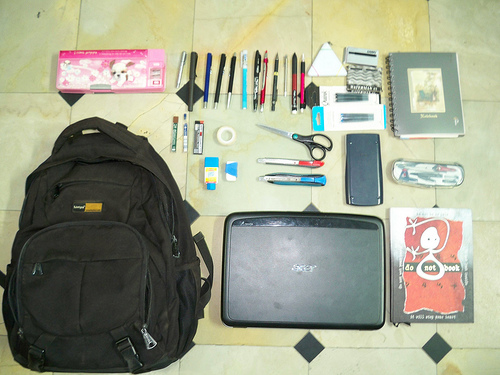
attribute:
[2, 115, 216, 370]
backpack — black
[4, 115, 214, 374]
bag — black, yellow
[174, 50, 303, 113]
pens — lined up, grouped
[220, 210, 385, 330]
laptop — closed, acer, blac, black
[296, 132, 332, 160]
handles — black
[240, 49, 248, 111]
pen — blue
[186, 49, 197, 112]
pen — black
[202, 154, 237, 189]
eraser — blue, white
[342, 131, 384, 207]
calculator — upside down, gray, blue, black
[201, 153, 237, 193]
erasers — blue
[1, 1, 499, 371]
tile — edged\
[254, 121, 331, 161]
scissors — black, silver, pair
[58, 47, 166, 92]
box — pink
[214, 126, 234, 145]
tape — white, clear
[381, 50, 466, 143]
notebook — spiral, blue, white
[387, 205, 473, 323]
book — black, red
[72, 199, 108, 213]
logo — black, orange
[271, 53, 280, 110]
pencil — mechanical, black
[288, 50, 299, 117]
marker — black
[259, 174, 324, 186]
white out — here